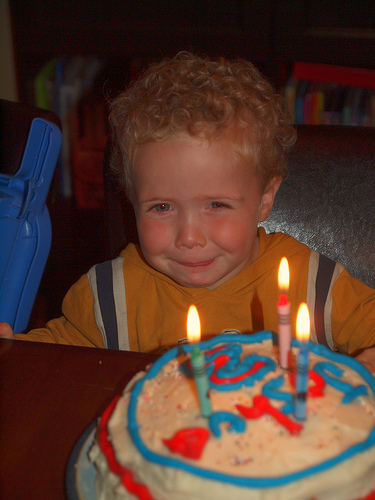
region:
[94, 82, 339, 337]
a boy with blonde hair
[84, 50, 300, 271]
a boy with curly hair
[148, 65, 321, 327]
a boy with blonde curly hair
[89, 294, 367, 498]
a small birthday cake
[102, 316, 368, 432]
a small round birthday cake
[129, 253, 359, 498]
a cake with candles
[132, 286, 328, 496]
three candles on the cake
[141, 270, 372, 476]
three candle on a birthday cae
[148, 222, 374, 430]
a birthday cake with candles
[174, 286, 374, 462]
three candles that are lit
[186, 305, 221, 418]
birthday candle shaped like a green crayon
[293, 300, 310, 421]
birthday candle shaped like a blue crayon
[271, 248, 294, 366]
birthday candle shaped like a red crayon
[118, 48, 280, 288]
boy is blond with curly hair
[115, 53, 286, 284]
boy is smiling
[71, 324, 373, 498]
red, white, and blue cake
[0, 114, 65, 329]
partially seen blue artifact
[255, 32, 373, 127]
books seen in background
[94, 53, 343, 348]
boy wearing orange shirt with white and black stripes on shoulders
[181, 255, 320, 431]
three candles lit on cake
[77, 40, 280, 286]
a small boy with curly hair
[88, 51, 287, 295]
a small boy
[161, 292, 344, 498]
a cake with crayon candles on it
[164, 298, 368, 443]
crayon candles lit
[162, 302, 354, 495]
crayon candles on a cake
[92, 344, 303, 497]
a cake with blue frosting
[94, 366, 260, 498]
a cake with red frosting on it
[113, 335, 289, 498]
a cake with sprinkles on it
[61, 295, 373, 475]
a cake on a table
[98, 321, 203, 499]
a cake with white frosting on it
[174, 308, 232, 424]
Candle on a cake.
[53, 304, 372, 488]
Small birthday cake.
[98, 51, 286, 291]
A little boy crying at his party.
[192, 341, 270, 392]
Number two on the cake.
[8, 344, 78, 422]
Table made of wood.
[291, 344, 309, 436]
Candle shaped like a crayon.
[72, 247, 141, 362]
Stripe on a boy's shirt.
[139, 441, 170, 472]
Blue icing on a cake.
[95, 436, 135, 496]
Red icing on a cake.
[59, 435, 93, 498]
Platter under a birthday cake.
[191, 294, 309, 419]
the candles on the cake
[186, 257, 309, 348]
the flames on the candles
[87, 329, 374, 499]
the frosting on the cake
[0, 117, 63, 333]
the blue plastic next to the boy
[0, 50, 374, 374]
the boy in front of the cake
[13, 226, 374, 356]
the shirt on the boy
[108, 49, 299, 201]
the hair on the boy's head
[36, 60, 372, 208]
the books behind the boy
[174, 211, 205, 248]
the nose on the boy's face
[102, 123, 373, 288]
the backrest of the chair